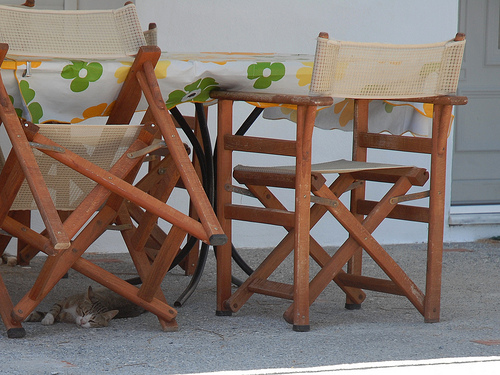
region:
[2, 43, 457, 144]
a white tablecloth with flowers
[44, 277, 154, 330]
a cat lying on the ground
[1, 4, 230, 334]
a chair tipped up against the table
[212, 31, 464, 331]
a wooden chair at the corner of the table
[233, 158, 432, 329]
a small wooden stool under the chair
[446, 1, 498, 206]
the corner of a gray door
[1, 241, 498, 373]
gray asphalt on the ground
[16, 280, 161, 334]
gray cat with a white face and paws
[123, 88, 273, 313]
black base supporting the table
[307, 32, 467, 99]
canvas on the back of the chair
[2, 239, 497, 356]
Grey colored carpet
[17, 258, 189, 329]
Grey and white kitten sleeping under the table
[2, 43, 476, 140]
White green and yellow table cloth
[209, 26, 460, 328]
Wooden chair with white mesh backing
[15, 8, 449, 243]
Wall painted with white paint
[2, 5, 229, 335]
Chair leaning on table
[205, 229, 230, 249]
Rubber bottom of chair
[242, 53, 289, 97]
One of several green flowers on tablecloth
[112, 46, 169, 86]
One of several yellow flowers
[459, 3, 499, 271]
White door and threshold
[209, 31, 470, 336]
wood and fabric directors chair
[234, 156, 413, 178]
beige fabric chair seat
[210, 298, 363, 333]
black tips on the end of wooden chair legs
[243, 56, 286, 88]
green flower on a table cloth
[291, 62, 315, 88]
yellow flower on a table cloth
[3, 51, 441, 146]
green yellow and white table cloth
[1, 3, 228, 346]
chair is tilted forward resting on a table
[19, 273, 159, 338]
cat is asleep under a tilted dining chair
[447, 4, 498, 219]
a grey external door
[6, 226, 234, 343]
two rubber tips are missing from chair legs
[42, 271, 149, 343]
a cat laying on the ground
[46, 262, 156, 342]
a cat laying under a table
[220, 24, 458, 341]
a wood folding chair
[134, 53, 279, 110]
a table cloth with a floral print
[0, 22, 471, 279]
two folding chairs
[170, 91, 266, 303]
black metal legs on a table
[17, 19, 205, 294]
a chair leaning over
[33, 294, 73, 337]
a cat with his front legs crossed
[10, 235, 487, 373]
a concrete walkway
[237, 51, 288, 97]
a green flower print on a table cloth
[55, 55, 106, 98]
flower design on a table cloth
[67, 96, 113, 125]
flower design on a table cloth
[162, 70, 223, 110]
flower design on a table cloth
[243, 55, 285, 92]
flower design on a table cloth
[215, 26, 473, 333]
wooden chair near a table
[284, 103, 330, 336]
wooden leg of a chair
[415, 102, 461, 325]
wooden leg of a chair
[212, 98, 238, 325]
wooden leg of a chair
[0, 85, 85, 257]
wooden leg of a chair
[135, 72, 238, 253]
wooden leg of a chair